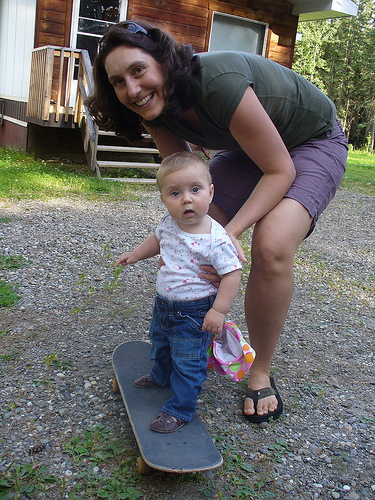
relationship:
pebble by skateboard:
[274, 472, 293, 490] [132, 339, 189, 430]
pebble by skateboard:
[302, 340, 371, 476] [104, 323, 224, 489]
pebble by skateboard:
[323, 492, 342, 498] [107, 331, 223, 472]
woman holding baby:
[72, 15, 353, 439] [134, 138, 245, 498]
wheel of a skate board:
[131, 451, 150, 476] [82, 329, 221, 446]